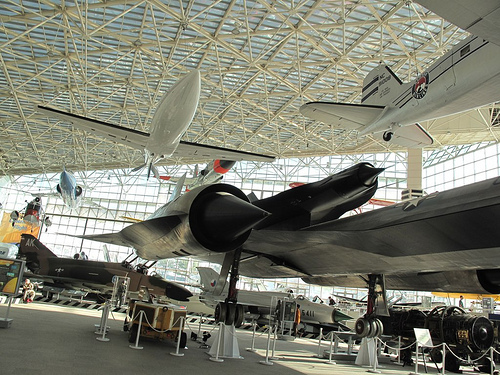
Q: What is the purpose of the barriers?
A: Keep out people.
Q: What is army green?
A: Aircraft in back.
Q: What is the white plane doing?
A: Hanging.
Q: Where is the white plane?
A: Above.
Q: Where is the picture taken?
A: Aircraft museum.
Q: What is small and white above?
A: Aircraft.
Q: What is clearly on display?
A: White aircraft.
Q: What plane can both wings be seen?
A: White aircraft.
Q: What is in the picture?
A: A plane exhibit.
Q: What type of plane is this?
A: SR-71 Blackbird.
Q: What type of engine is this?
A: A jet engine.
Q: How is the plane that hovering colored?
A: White.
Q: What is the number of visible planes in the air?
A: Five.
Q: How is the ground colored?
A: Gray.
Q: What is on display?
A: Aircraft.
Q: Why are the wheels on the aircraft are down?
A: For display.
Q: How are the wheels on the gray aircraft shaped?
A: Round.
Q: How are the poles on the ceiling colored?
A: White.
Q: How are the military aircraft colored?
A: Green and gray.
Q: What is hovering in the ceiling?
A: A white plane.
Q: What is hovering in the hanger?
A: A white plane.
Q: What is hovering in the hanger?
A: A white plane.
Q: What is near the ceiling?
A: A white plane.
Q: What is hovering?
A: A white plane.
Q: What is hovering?
A: A white plane.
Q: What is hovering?
A: A white plane.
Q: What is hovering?
A: A white plane.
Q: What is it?
A: Planes.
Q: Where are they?
A: Museum.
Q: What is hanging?
A: Plane.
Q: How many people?
A: 0.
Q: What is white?
A: Plane.